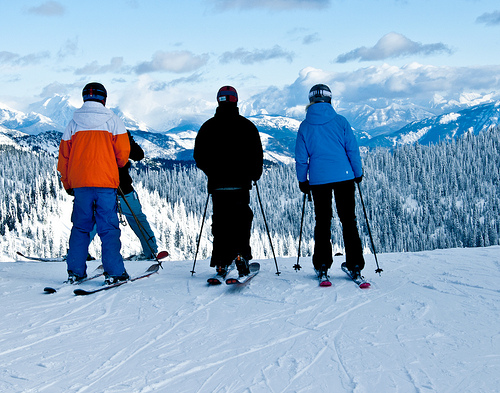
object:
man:
[65, 128, 157, 259]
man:
[192, 84, 264, 271]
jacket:
[192, 104, 262, 189]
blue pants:
[63, 187, 125, 281]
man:
[57, 80, 129, 283]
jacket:
[55, 101, 129, 189]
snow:
[0, 245, 498, 392]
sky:
[1, 0, 498, 130]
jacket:
[113, 131, 142, 195]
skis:
[43, 252, 150, 293]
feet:
[66, 271, 88, 281]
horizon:
[0, 79, 496, 151]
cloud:
[0, 0, 500, 143]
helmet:
[80, 82, 107, 104]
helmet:
[214, 86, 238, 107]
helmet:
[308, 83, 335, 105]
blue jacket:
[293, 101, 361, 189]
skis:
[207, 262, 258, 286]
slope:
[3, 244, 495, 393]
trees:
[480, 201, 489, 215]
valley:
[0, 59, 492, 255]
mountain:
[0, 93, 499, 176]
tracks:
[45, 283, 313, 390]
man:
[294, 83, 363, 274]